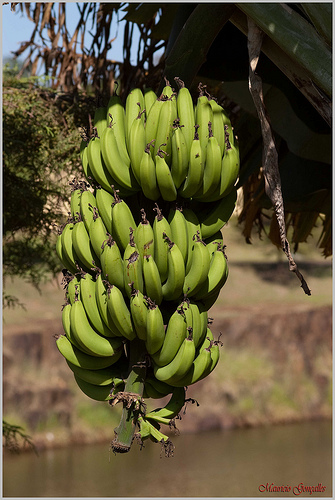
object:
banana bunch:
[56, 188, 238, 306]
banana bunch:
[56, 273, 220, 454]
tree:
[3, 58, 84, 309]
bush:
[267, 382, 292, 403]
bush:
[220, 352, 266, 379]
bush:
[229, 394, 257, 414]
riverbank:
[192, 400, 333, 429]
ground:
[246, 96, 276, 133]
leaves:
[11, 101, 72, 194]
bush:
[2, 56, 89, 313]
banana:
[192, 136, 221, 200]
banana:
[187, 134, 205, 188]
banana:
[177, 87, 196, 164]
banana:
[127, 119, 145, 186]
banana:
[100, 125, 140, 191]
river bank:
[3, 303, 332, 450]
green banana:
[106, 98, 131, 167]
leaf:
[245, 21, 313, 299]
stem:
[128, 281, 137, 297]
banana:
[130, 290, 150, 341]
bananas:
[163, 240, 185, 304]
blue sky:
[4, 7, 160, 77]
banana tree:
[1, 0, 334, 455]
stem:
[214, 332, 223, 347]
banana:
[172, 348, 211, 387]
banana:
[56, 335, 123, 370]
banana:
[106, 94, 130, 167]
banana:
[153, 215, 173, 283]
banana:
[193, 251, 226, 301]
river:
[7, 429, 332, 497]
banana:
[155, 155, 177, 202]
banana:
[139, 150, 160, 200]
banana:
[87, 136, 134, 197]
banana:
[55, 335, 118, 370]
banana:
[197, 148, 238, 202]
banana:
[145, 305, 165, 355]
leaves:
[4, 3, 172, 97]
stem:
[139, 207, 152, 225]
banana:
[112, 200, 137, 251]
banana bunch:
[80, 85, 240, 201]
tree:
[147, 4, 333, 275]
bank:
[221, 312, 324, 421]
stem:
[108, 390, 142, 409]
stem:
[173, 77, 188, 90]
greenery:
[2, 61, 86, 319]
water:
[2, 417, 322, 497]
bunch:
[56, 82, 241, 452]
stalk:
[112, 343, 148, 453]